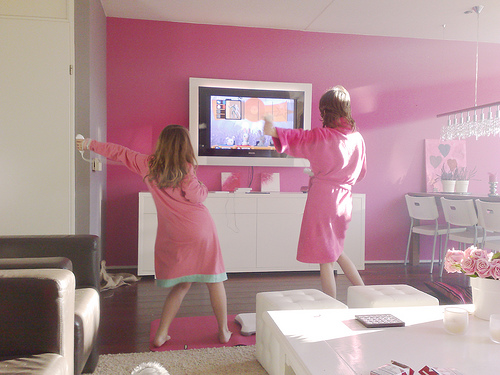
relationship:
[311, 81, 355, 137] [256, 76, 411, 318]
head of woman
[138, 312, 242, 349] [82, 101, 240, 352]
foot of girl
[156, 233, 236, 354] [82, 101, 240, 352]
leg of girl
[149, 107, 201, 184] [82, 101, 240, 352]
head of girl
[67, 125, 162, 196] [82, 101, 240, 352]
arm of girl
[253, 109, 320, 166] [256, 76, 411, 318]
arm of woman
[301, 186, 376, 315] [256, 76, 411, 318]
leg of woman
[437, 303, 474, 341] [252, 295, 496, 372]
glass on table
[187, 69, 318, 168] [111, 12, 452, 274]
tv on wall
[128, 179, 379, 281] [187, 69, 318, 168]
cabinet below tv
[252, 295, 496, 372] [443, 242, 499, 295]
table with flowers